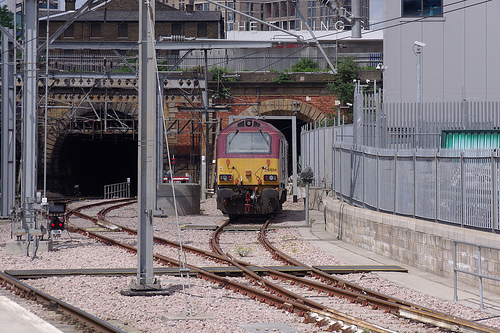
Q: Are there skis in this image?
A: No, there are no skis.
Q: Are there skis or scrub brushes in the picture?
A: No, there are no skis or scrub brushes.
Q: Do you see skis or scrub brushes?
A: No, there are no skis or scrub brushes.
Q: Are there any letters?
A: Yes, there are letters.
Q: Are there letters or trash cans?
A: Yes, there are letters.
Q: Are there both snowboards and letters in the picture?
A: No, there are letters but no snowboards.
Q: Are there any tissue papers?
A: No, there are no tissue papers.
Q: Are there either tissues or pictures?
A: No, there are no tissues or pictures.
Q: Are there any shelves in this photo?
A: No, there are no shelves.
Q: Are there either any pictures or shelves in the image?
A: No, there are no shelves or pictures.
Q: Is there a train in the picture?
A: Yes, there is a train.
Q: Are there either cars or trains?
A: Yes, there is a train.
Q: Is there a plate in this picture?
A: Yes, there is a plate.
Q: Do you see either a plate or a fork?
A: Yes, there is a plate.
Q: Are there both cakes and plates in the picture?
A: No, there is a plate but no cakes.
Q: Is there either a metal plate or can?
A: Yes, there is a metal plate.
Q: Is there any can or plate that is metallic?
A: Yes, the plate is metallic.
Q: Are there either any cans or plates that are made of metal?
A: Yes, the plate is made of metal.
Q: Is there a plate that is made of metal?
A: Yes, there is a plate that is made of metal.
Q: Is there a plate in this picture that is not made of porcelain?
A: Yes, there is a plate that is made of metal.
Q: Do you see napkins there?
A: No, there are no napkins.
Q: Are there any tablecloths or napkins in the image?
A: No, there are no napkins or tablecloths.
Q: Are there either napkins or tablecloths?
A: No, there are no napkins or tablecloths.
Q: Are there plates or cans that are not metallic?
A: No, there is a plate but it is metallic.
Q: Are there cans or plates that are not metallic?
A: No, there is a plate but it is metallic.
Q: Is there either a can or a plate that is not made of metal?
A: No, there is a plate but it is made of metal.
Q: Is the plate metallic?
A: Yes, the plate is metallic.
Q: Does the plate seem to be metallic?
A: Yes, the plate is metallic.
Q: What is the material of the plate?
A: The plate is made of metal.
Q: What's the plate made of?
A: The plate is made of metal.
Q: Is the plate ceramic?
A: No, the plate is metallic.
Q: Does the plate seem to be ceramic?
A: No, the plate is metallic.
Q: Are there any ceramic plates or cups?
A: No, there is a plate but it is metallic.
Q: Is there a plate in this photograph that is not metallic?
A: No, there is a plate but it is metallic.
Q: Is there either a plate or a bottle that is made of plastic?
A: No, there is a plate but it is made of metal.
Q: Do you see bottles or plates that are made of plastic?
A: No, there is a plate but it is made of metal.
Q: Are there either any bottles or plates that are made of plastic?
A: No, there is a plate but it is made of metal.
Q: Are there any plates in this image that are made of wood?
A: No, there is a plate but it is made of metal.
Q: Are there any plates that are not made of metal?
A: No, there is a plate but it is made of metal.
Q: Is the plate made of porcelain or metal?
A: The plate is made of metal.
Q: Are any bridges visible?
A: Yes, there is a bridge.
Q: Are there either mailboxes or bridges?
A: Yes, there is a bridge.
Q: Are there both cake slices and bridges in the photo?
A: No, there is a bridge but no cake slices.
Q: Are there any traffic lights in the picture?
A: No, there are no traffic lights.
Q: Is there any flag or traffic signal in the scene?
A: No, there are no traffic lights or flags.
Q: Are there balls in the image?
A: No, there are no balls.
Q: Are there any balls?
A: No, there are no balls.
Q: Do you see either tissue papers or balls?
A: No, there are no balls or tissue papers.